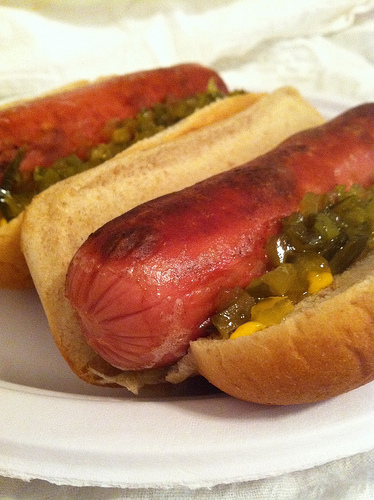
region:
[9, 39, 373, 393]
two hotdogs next to each other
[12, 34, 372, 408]
two cooked hotdogs next to each other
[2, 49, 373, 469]
two hotdogs in buns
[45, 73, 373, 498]
hotdog on a plate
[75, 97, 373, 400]
a cooked hotdog in a bun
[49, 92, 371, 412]
a cooked hotdog with relish and mustard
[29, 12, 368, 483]
two hotdogs on a plate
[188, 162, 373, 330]
green relish on hotdog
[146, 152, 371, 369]
yellow mustard on hotdog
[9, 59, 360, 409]
hot dogs on paper plate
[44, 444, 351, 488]
rough edge on plate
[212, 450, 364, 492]
woven white material under plate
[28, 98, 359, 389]
hot dog between split roll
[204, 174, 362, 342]
relish and mustard on side of hot dog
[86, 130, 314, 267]
charred marks on surface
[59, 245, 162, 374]
wrinkles toward end where skin is broken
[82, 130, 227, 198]
pockets of air inside the bread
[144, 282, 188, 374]
oily foam on end of hot dog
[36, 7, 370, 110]
fabric in folds behind plate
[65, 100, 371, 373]
The in focus hot dog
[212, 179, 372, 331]
The relish on the in focus hot dog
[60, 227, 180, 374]
The end of the in focus hot dog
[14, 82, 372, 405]
The bun of the in focus hot dog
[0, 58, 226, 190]
The out of focus hot dog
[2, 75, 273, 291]
The bun of the out of focus hot dog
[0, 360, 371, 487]
The rim of the plate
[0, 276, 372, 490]
The plate holding the hot dogs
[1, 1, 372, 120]
The cloth in the background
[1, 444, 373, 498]
The cloth under the plate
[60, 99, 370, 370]
a roasted hotdog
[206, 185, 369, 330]
green relish next to a hotdog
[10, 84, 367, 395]
a bun holding a hotdog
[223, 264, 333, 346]
yellow mustard under relish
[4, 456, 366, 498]
a white table cloth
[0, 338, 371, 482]
a white disposable plate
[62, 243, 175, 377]
the wrinkled end of a hotdog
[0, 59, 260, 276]
a second hotdog and bun behind another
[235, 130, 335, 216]
a blister on a hotdog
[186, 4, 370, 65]
a wrinkled napkin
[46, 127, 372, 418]
a sandwich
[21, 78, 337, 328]
a sandwich